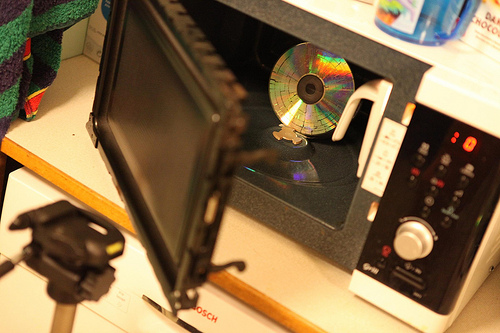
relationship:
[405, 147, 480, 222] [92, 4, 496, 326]
button on microwave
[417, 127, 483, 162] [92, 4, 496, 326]
digit on microwave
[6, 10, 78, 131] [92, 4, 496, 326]
cloth near microwave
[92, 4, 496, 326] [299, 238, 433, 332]
microwave has edge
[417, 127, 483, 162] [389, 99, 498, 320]
digit on panel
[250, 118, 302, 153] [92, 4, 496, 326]
turntable inside microwave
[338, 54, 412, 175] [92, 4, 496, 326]
handle inside microwave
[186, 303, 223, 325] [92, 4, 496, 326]
word under microwave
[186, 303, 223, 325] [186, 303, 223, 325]
word written word